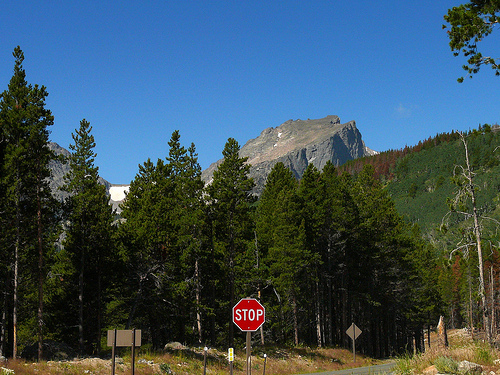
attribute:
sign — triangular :
[231, 297, 268, 332]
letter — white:
[231, 307, 241, 322]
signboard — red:
[223, 291, 263, 331]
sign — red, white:
[228, 290, 266, 348]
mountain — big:
[198, 114, 378, 194]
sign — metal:
[105, 329, 143, 348]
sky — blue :
[338, 31, 402, 83]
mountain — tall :
[202, 112, 381, 182]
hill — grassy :
[277, 133, 494, 327]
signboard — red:
[227, 292, 269, 339]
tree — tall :
[201, 135, 258, 352]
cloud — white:
[390, 104, 412, 116]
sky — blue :
[4, 7, 461, 122]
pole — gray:
[243, 329, 253, 374]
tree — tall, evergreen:
[112, 158, 214, 345]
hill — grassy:
[0, 346, 375, 371]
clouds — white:
[155, 44, 320, 126]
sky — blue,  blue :
[0, 0, 497, 185]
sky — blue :
[99, 16, 477, 160]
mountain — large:
[173, 96, 385, 206]